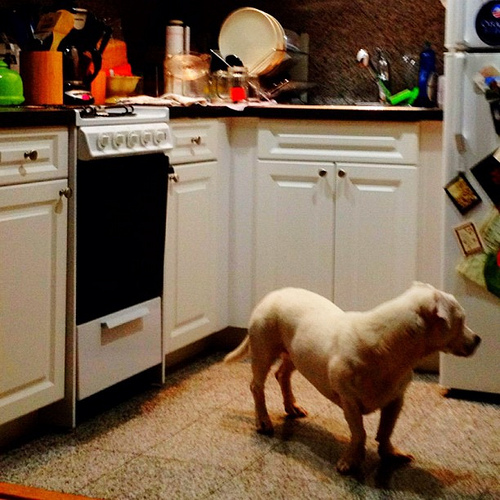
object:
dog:
[227, 279, 480, 475]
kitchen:
[3, 1, 500, 497]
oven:
[70, 117, 171, 429]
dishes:
[215, 7, 286, 78]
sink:
[284, 92, 431, 113]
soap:
[419, 48, 439, 107]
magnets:
[445, 172, 486, 256]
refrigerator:
[441, 0, 500, 402]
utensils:
[28, 9, 72, 108]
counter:
[2, 98, 271, 127]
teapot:
[0, 62, 27, 105]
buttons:
[96, 128, 168, 151]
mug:
[215, 65, 252, 105]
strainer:
[210, 49, 317, 104]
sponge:
[390, 87, 420, 105]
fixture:
[358, 46, 393, 104]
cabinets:
[167, 122, 434, 365]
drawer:
[168, 120, 225, 165]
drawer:
[0, 127, 70, 188]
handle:
[447, 0, 470, 155]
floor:
[3, 346, 500, 497]